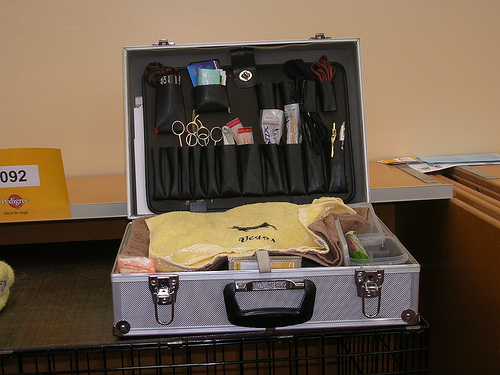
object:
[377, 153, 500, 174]
papers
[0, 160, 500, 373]
desk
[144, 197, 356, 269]
towel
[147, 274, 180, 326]
latch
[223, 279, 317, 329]
handle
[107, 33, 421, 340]
brief case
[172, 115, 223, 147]
handles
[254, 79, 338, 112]
pocket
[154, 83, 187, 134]
pocket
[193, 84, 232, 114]
pocket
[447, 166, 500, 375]
ground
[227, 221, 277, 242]
logo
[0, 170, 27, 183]
092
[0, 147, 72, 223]
envelope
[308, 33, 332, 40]
latch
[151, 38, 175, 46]
latch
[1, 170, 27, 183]
numbers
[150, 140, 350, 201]
pocket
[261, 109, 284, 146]
cream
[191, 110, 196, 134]
scissors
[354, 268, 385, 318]
latch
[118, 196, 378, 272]
contents